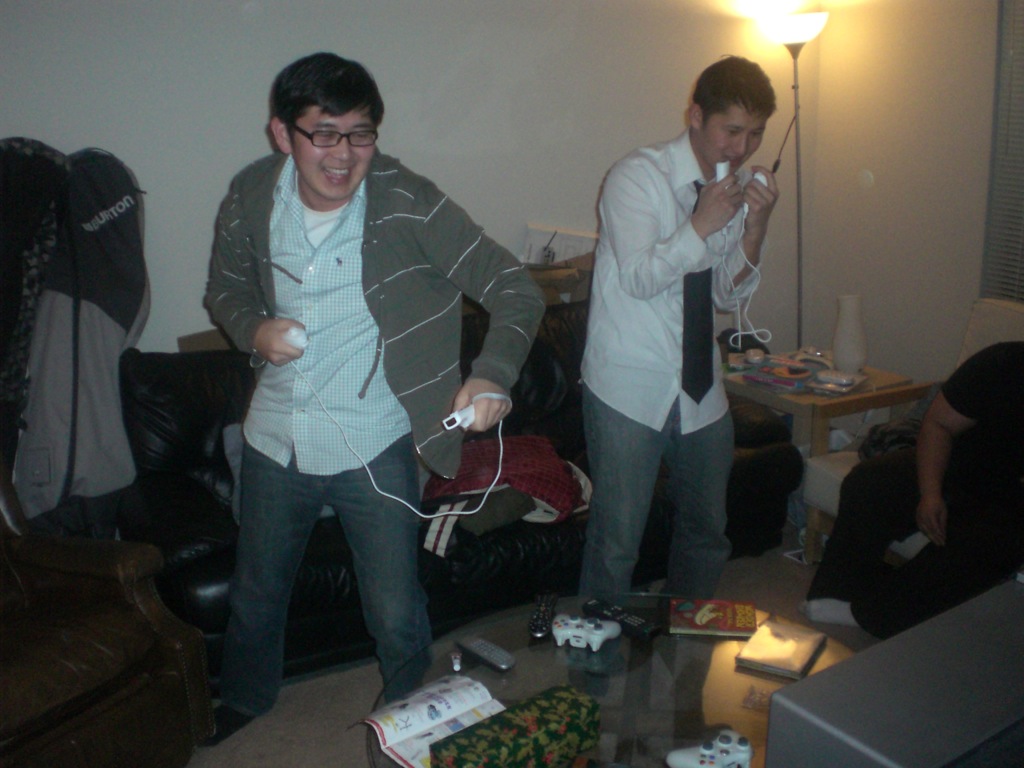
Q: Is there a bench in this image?
A: No, there are no benches.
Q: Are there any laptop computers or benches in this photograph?
A: No, there are no benches or laptop computers.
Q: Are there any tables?
A: Yes, there is a table.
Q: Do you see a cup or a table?
A: Yes, there is a table.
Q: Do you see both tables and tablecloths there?
A: No, there is a table but no tablecloths.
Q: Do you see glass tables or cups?
A: Yes, there is a glass table.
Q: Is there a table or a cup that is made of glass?
A: Yes, the table is made of glass.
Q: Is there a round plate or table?
A: Yes, there is a round table.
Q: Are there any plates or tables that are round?
A: Yes, the table is round.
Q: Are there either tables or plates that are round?
A: Yes, the table is round.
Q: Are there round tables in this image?
A: Yes, there is a round table.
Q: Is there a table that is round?
A: Yes, there is a table that is round.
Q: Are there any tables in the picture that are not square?
A: Yes, there is a round table.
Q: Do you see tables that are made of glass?
A: Yes, there is a table that is made of glass.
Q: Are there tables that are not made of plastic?
A: Yes, there is a table that is made of glass.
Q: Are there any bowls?
A: No, there are no bowls.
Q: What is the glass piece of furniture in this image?
A: The piece of furniture is a table.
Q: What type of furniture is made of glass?
A: The furniture is a table.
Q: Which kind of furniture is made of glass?
A: The furniture is a table.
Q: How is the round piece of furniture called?
A: The piece of furniture is a table.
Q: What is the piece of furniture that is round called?
A: The piece of furniture is a table.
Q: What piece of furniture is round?
A: The piece of furniture is a table.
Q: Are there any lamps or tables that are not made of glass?
A: No, there is a table but it is made of glass.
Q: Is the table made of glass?
A: Yes, the table is made of glass.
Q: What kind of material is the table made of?
A: The table is made of glass.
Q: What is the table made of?
A: The table is made of glass.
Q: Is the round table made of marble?
A: No, the table is made of glass.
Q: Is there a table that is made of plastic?
A: No, there is a table but it is made of glass.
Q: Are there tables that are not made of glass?
A: No, there is a table but it is made of glass.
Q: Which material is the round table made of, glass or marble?
A: The table is made of glass.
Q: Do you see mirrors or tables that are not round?
A: No, there is a table but it is round.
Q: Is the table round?
A: Yes, the table is round.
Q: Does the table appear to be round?
A: Yes, the table is round.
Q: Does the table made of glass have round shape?
A: Yes, the table is round.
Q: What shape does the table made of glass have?
A: The table has round shape.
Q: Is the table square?
A: No, the table is round.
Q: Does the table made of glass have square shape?
A: No, the table is round.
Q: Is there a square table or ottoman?
A: No, there is a table but it is round.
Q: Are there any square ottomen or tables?
A: No, there is a table but it is round.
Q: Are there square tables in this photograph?
A: No, there is a table but it is round.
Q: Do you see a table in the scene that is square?
A: No, there is a table but it is round.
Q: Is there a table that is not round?
A: No, there is a table but it is round.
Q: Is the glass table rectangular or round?
A: The table is round.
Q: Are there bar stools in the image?
A: No, there are no bar stools.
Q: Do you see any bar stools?
A: No, there are no bar stools.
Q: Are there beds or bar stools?
A: No, there are no bar stools or beds.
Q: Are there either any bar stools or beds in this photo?
A: No, there are no bar stools or beds.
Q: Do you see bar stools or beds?
A: No, there are no bar stools or beds.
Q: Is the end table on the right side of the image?
A: Yes, the end table is on the right of the image.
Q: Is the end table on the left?
A: No, the end table is on the right of the image.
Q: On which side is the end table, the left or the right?
A: The end table is on the right of the image.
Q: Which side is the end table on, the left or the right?
A: The end table is on the right of the image.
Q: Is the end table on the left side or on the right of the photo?
A: The end table is on the right of the image.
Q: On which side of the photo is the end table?
A: The end table is on the right of the image.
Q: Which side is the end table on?
A: The end table is on the right of the image.